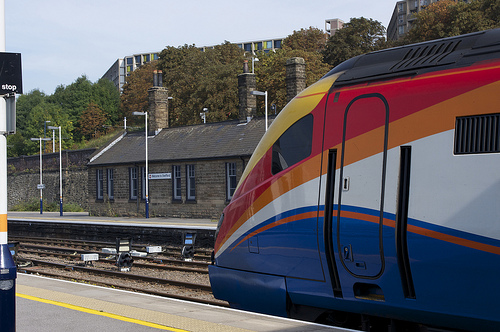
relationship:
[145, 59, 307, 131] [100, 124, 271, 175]
chimneys on roof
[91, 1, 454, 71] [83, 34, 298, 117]
buildings behind trees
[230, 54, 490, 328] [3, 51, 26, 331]
train on pole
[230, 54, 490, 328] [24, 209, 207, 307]
train on tracks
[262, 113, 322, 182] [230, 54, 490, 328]
window on train